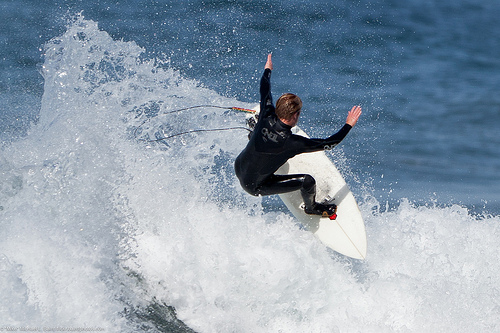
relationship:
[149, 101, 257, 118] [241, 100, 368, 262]
cables extended from surfboard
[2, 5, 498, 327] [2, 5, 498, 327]
ocean in ocean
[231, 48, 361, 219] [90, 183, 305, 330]
man makes waves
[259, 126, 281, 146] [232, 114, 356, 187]
writing on t-shirt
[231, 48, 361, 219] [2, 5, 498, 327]
man in ocean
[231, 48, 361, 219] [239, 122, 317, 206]
man wears wetsuit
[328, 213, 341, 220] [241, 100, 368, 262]
red spot on surfboard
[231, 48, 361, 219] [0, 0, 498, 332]
man riding waves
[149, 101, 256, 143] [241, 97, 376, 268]
cables behind surfboard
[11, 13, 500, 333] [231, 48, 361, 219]
splash behind man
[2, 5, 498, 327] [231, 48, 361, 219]
ocean behind man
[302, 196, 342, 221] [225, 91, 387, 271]
feet on surfboard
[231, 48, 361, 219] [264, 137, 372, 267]
man on surf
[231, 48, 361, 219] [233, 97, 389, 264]
man on surfboard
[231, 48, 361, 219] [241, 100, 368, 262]
man on surfboard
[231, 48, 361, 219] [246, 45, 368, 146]
man has arms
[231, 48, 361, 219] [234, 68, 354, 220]
man has wetsuit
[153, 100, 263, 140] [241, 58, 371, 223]
cables near surfer